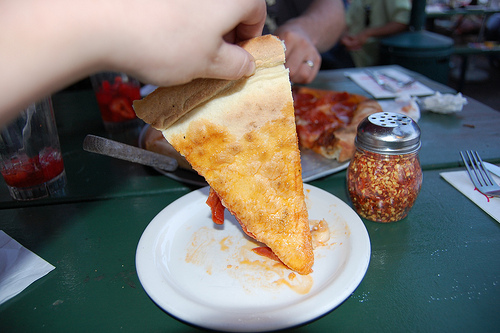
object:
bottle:
[343, 109, 424, 223]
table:
[0, 62, 499, 331]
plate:
[128, 170, 373, 327]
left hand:
[269, 22, 323, 86]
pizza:
[142, 124, 192, 171]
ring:
[302, 58, 315, 67]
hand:
[272, 22, 323, 85]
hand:
[0, 0, 268, 88]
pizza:
[130, 33, 315, 276]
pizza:
[290, 83, 383, 163]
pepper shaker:
[344, 109, 425, 223]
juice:
[179, 217, 331, 294]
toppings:
[203, 186, 227, 225]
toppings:
[245, 211, 333, 285]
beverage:
[0, 143, 66, 190]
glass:
[0, 94, 69, 202]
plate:
[123, 164, 383, 324]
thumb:
[194, 38, 259, 82]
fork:
[455, 148, 500, 199]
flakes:
[344, 145, 425, 223]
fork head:
[455, 148, 499, 198]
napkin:
[437, 160, 499, 225]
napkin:
[0, 227, 57, 303]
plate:
[134, 181, 371, 331]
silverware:
[374, 68, 419, 87]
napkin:
[339, 63, 437, 100]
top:
[351, 109, 423, 156]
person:
[0, 0, 269, 127]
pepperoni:
[295, 87, 362, 151]